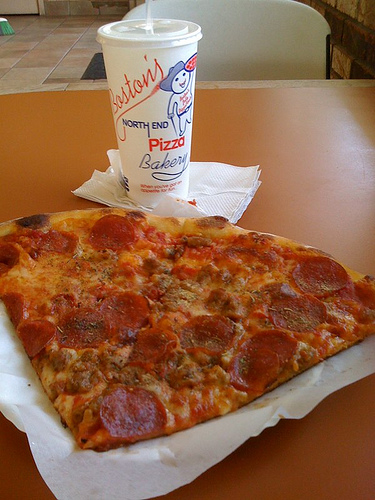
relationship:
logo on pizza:
[114, 80, 185, 157] [49, 238, 295, 409]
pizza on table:
[49, 238, 295, 409] [227, 72, 342, 123]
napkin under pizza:
[208, 156, 261, 213] [49, 238, 295, 409]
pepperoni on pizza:
[237, 318, 286, 378] [49, 238, 295, 409]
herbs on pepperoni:
[53, 342, 67, 362] [237, 318, 286, 378]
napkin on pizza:
[208, 156, 261, 213] [49, 238, 295, 409]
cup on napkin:
[107, 32, 192, 198] [208, 156, 261, 213]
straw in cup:
[144, 0, 160, 15] [107, 32, 192, 198]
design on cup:
[127, 47, 189, 174] [107, 32, 192, 198]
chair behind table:
[232, 5, 308, 76] [227, 72, 342, 123]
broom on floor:
[4, 22, 18, 42] [42, 26, 63, 37]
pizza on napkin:
[49, 238, 295, 409] [208, 156, 261, 213]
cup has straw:
[107, 32, 192, 198] [144, 0, 160, 15]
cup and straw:
[107, 32, 192, 198] [144, 0, 160, 15]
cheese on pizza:
[141, 276, 198, 308] [49, 238, 295, 409]